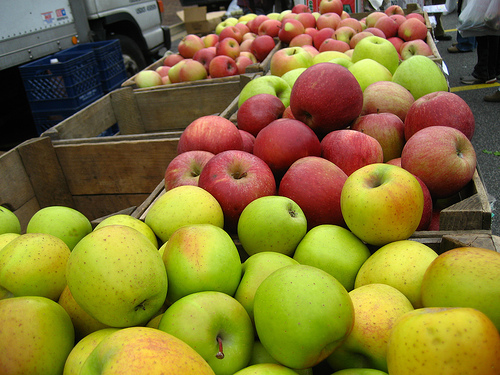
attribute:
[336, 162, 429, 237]
green apple — fresh looking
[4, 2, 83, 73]
side — metal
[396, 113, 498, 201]
apple — fresh looking, pink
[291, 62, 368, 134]
apple — red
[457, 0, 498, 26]
shirt — white, man's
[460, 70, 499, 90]
shoe — grey, gym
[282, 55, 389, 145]
apple — red, top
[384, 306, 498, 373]
apple — yellow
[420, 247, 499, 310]
apple — yellow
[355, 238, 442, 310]
apple — yellow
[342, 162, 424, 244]
apple — yellow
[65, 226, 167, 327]
apple — yellow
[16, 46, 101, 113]
crate — blue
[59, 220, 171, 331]
apple — green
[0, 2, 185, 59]
truck — white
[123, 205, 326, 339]
green apples — pile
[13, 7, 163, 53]
truck — parked, white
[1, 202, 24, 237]
apple — green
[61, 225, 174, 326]
apple — fresh looking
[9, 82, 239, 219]
crates — empty, wooden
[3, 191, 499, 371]
apples — yellow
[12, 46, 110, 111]
tray — blue, plastic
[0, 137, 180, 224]
tray — wooden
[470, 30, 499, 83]
pants — black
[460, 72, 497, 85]
shoes — tennis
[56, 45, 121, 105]
crates — blue, milk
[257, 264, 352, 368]
fruit — green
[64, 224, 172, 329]
fruit — green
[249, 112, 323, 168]
apple — pink, fresh looking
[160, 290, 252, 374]
fruit — green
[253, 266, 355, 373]
apple — fresh looking, green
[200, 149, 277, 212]
apple — red, dark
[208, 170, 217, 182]
spot — small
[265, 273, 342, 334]
spots — reddish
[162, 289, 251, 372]
apple — green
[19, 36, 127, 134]
crates — blue, plastic, stacked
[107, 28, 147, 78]
tyre — vehicle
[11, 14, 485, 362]
cases — several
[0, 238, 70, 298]
apple — green, fresh looking